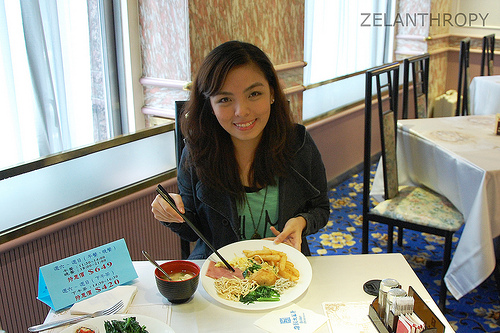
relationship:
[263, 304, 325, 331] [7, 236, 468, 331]
napkin laying flat on table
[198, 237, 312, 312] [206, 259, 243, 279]
plate full of food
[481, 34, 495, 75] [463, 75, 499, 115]
chair pulled up to table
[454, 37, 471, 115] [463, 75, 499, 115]
chair pulled up to table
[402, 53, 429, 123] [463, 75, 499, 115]
chair pulled up to table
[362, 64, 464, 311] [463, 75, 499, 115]
chair pulled up to table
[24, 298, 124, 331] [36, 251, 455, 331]
fork on a table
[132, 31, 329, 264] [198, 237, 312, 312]
woman holding plate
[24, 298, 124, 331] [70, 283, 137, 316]
fork placed on a towel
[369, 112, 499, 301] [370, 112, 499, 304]
tablecloth spread on table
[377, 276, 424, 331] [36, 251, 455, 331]
spices placed on table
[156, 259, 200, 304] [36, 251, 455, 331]
bowl sitting on table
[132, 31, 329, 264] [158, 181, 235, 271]
woman holding chopsticks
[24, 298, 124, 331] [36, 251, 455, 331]
fork on table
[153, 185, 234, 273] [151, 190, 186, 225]
chopsticks are in hand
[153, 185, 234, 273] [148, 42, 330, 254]
chopsticks being held by woman